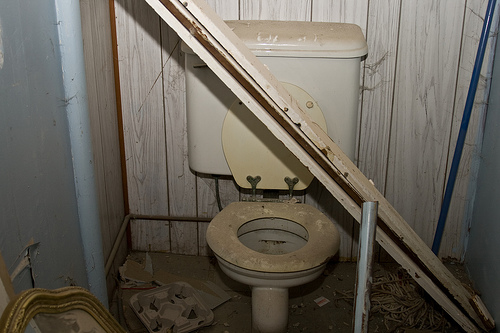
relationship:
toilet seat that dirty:
[218, 200, 328, 270] [258, 202, 270, 215]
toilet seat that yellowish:
[218, 200, 328, 270] [215, 218, 233, 254]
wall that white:
[395, 18, 457, 116] [375, 13, 383, 32]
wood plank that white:
[241, 82, 295, 138] [375, 13, 383, 32]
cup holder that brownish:
[134, 288, 203, 329] [174, 280, 190, 294]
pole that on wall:
[467, 51, 483, 124] [395, 18, 457, 116]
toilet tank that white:
[279, 37, 358, 88] [375, 13, 383, 32]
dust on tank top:
[350, 25, 359, 39] [246, 20, 371, 63]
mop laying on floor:
[379, 274, 425, 327] [300, 302, 332, 332]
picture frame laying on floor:
[35, 289, 108, 323] [300, 302, 332, 332]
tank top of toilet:
[246, 20, 371, 63] [193, 28, 329, 283]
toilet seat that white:
[218, 200, 328, 270] [375, 13, 383, 32]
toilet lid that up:
[229, 110, 266, 180] [220, 95, 316, 276]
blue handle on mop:
[445, 40, 483, 165] [379, 274, 425, 327]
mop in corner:
[379, 274, 425, 327] [484, 39, 500, 107]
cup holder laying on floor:
[134, 288, 203, 329] [300, 302, 332, 332]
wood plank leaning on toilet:
[241, 82, 295, 138] [193, 28, 329, 283]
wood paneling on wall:
[121, 38, 156, 158] [395, 18, 457, 116]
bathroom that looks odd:
[36, 6, 475, 313] [131, 250, 417, 323]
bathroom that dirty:
[36, 6, 475, 313] [258, 202, 270, 215]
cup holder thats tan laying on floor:
[134, 288, 203, 329] [300, 302, 332, 332]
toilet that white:
[193, 28, 329, 283] [375, 13, 383, 32]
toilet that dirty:
[193, 28, 329, 283] [258, 202, 270, 215]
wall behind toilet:
[395, 18, 457, 116] [193, 28, 329, 283]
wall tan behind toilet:
[395, 18, 457, 116] [193, 28, 329, 283]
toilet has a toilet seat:
[193, 28, 329, 283] [218, 200, 328, 270]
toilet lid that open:
[229, 110, 266, 180] [220, 95, 316, 276]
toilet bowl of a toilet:
[256, 224, 288, 251] [193, 28, 329, 283]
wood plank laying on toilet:
[241, 82, 295, 138] [193, 28, 329, 283]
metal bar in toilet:
[354, 196, 377, 315] [193, 28, 329, 283]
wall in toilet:
[395, 18, 457, 116] [193, 28, 329, 283]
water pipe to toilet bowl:
[209, 174, 228, 214] [256, 224, 288, 251]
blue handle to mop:
[445, 40, 483, 165] [379, 274, 425, 327]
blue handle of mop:
[445, 40, 483, 165] [379, 274, 425, 327]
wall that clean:
[395, 18, 457, 116] [11, 37, 41, 85]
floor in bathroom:
[300, 302, 332, 332] [36, 6, 475, 313]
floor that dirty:
[300, 302, 332, 332] [258, 202, 270, 215]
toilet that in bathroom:
[193, 28, 329, 283] [36, 6, 475, 313]